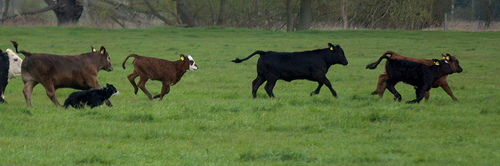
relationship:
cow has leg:
[119, 52, 203, 101] [155, 76, 171, 100]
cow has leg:
[229, 42, 351, 99] [250, 74, 264, 97]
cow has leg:
[229, 42, 351, 99] [263, 77, 278, 97]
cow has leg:
[229, 42, 351, 99] [317, 74, 337, 96]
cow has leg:
[229, 42, 351, 99] [309, 82, 324, 96]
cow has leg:
[229, 42, 351, 99] [386, 79, 402, 103]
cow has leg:
[3, 41, 122, 112] [40, 79, 60, 107]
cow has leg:
[8, 41, 113, 109] [21, 77, 36, 104]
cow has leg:
[121, 52, 196, 101] [135, 74, 155, 98]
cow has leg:
[229, 42, 351, 99] [309, 77, 324, 95]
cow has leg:
[229, 42, 351, 99] [325, 76, 338, 100]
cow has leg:
[229, 42, 351, 99] [440, 81, 457, 101]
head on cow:
[325, 37, 350, 68] [222, 31, 350, 105]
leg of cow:
[385, 77, 401, 102] [365, 50, 452, 102]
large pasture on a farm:
[5, 22, 461, 160] [3, 0, 493, 159]